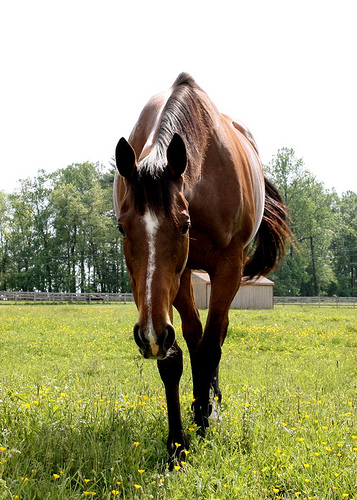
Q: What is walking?
A: Horse.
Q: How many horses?
A: One.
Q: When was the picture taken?
A: Daytime.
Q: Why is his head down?
A: To eat.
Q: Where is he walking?
A: Field.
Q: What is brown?
A: Horse.